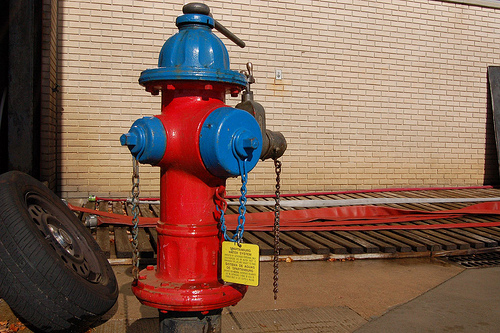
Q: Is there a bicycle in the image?
A: No, there are no bicycles.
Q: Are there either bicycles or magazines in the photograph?
A: No, there are no bicycles or magazines.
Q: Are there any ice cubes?
A: No, there are no ice cubes.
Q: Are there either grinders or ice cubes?
A: No, there are no ice cubes or grinders.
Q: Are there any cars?
A: No, there are no cars.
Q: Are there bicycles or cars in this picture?
A: No, there are no cars or bicycles.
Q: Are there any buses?
A: No, there are no buses.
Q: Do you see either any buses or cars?
A: No, there are no buses or cars.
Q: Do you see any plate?
A: No, there are no plates.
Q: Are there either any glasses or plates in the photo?
A: No, there are no plates or glasses.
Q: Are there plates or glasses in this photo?
A: No, there are no plates or glasses.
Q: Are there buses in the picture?
A: No, there are no buses.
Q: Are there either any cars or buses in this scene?
A: No, there are no buses or cars.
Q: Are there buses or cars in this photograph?
A: No, there are no buses or cars.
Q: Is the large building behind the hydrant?
A: Yes, the building is behind the hydrant.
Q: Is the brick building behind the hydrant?
A: Yes, the building is behind the hydrant.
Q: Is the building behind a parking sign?
A: No, the building is behind the hydrant.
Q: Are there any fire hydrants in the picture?
A: Yes, there is a fire hydrant.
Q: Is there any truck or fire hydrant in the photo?
A: Yes, there is a fire hydrant.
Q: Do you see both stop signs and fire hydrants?
A: No, there is a fire hydrant but no stop signs.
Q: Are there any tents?
A: No, there are no tents.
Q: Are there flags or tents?
A: No, there are no tents or flags.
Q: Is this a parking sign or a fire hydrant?
A: This is a fire hydrant.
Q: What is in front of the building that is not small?
A: The hydrant is in front of the building.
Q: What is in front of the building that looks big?
A: The hydrant is in front of the building.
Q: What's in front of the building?
A: The hydrant is in front of the building.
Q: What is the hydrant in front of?
A: The hydrant is in front of the building.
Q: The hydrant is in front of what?
A: The hydrant is in front of the building.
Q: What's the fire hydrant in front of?
A: The hydrant is in front of the building.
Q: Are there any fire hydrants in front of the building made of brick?
A: Yes, there is a fire hydrant in front of the building.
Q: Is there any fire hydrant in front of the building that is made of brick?
A: Yes, there is a fire hydrant in front of the building.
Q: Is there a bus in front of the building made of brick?
A: No, there is a fire hydrant in front of the building.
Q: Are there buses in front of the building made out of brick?
A: No, there is a fire hydrant in front of the building.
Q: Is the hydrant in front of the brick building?
A: Yes, the hydrant is in front of the building.